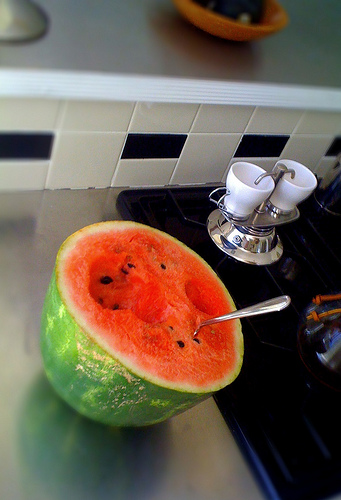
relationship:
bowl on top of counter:
[171, 1, 289, 43] [0, 0, 338, 112]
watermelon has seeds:
[38, 221, 245, 433] [92, 261, 222, 351]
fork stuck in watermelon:
[192, 294, 291, 336] [38, 221, 245, 433]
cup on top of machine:
[225, 162, 273, 218] [208, 163, 301, 265]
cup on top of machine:
[271, 158, 317, 214] [208, 163, 301, 265]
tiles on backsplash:
[0, 96, 338, 193] [1, 93, 340, 194]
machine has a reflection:
[208, 163, 301, 265] [223, 230, 265, 264]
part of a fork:
[264, 295, 292, 312] [192, 294, 291, 336]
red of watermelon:
[62, 227, 241, 383] [38, 221, 245, 433]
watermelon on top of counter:
[38, 221, 245, 433] [0, 186, 276, 499]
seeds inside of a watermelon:
[92, 261, 222, 351] [38, 221, 245, 433]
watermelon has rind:
[38, 221, 245, 433] [43, 268, 246, 430]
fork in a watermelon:
[192, 294, 291, 336] [38, 221, 245, 433]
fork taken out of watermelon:
[192, 294, 291, 336] [38, 221, 245, 433]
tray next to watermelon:
[108, 186, 337, 500] [38, 221, 245, 433]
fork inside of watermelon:
[192, 294, 291, 336] [38, 221, 245, 433]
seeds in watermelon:
[92, 261, 222, 351] [38, 221, 245, 433]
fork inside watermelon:
[192, 294, 291, 336] [38, 221, 245, 433]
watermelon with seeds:
[38, 221, 245, 433] [92, 261, 222, 351]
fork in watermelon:
[192, 294, 291, 336] [38, 221, 245, 433]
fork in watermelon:
[183, 296, 289, 334] [38, 221, 245, 433]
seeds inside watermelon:
[92, 261, 222, 351] [38, 221, 245, 433]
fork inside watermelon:
[183, 296, 289, 334] [38, 221, 245, 433]